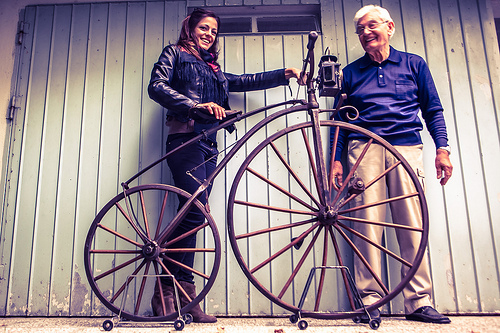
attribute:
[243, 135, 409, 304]
wheel — metal, large, big, rusty, parted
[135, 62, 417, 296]
bike — old, old fashioned, antique, rusty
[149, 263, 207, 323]
boots — brown, womans, fashionable, parted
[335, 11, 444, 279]
man — standing, older, smiling, old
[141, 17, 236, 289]
woman — pretty, smiling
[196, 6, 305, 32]
window — small, 2 paned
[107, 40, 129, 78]
door — hinged, large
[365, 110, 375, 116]
blue shirt — button up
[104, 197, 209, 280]
wheel — small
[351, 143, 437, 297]
tan pants — baggy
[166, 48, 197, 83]
leather jacket — shiny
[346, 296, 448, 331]
loafers — mans, black, edged